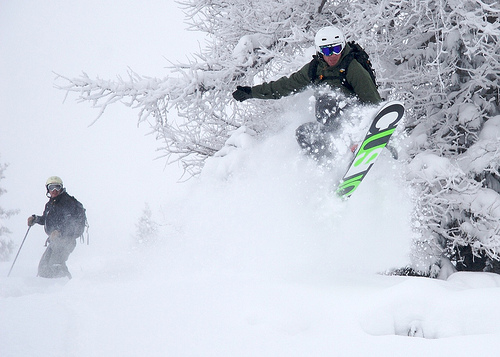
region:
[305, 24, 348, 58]
the helmet is white in color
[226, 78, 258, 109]
the hand has gloves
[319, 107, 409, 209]
the skateboard is green and white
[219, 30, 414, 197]
the skteboarder is in the air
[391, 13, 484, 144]
snow is on the tree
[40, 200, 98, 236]
the guy has a back pack on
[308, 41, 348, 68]
the goggles are white in color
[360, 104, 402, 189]
letters are n the surfboard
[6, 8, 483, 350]
the season is winter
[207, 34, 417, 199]
one hand is strecthed for balance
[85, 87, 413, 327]
cloud of snow in the air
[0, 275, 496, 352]
snow covered floor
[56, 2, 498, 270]
large tree covered in ice and snow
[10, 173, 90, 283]
man standing on the ground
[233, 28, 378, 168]
man in the air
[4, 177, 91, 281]
man holding ski poles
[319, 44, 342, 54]
blue and white goggles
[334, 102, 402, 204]
white, black and green snowboard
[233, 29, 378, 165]
man performing a trick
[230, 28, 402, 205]
man on snowboard in the air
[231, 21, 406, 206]
Man snowboarding on mountain.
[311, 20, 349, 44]
Man wearing white safety helmet.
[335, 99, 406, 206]
Snowboard attached to man's feet.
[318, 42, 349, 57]
Man wearing blue goggles.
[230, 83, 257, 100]
Man wearing green and black glove on hand.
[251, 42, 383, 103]
Man dressed in green jacket.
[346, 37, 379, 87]
Man carrying black pack on back.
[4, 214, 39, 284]
Skier carrying ski pole in hand.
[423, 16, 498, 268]
Snow covered pine tree.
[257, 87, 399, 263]
Kicked up snow from snowborder.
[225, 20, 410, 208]
A man snowboarding.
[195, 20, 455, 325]
Snow kicked up by the skiboarder.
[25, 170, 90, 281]
A man standing in the snow.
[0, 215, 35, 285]
The man is holding a ski pole.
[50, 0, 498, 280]
Tree limbs covered with snow.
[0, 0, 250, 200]
The sky is overcast.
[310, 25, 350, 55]
A white helmet on the man's head.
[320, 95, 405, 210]
Bottom of snowboard has green and black letters.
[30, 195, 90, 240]
The man is wearing a black coat.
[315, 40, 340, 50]
A man wearng blue tinted ski goggles.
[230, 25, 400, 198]
a snowboarder catching air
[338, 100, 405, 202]
a custom designed snowboard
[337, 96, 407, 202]
the snowboard is painted green, black and white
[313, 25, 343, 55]
a white ski helmet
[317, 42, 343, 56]
blue lens ski goggles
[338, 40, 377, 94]
the skier has a black back pack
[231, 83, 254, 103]
the skier is wearing black ski gloves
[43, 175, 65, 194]
a yellow ski helmet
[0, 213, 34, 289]
a black ski pole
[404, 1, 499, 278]
snow covered trees on the trail